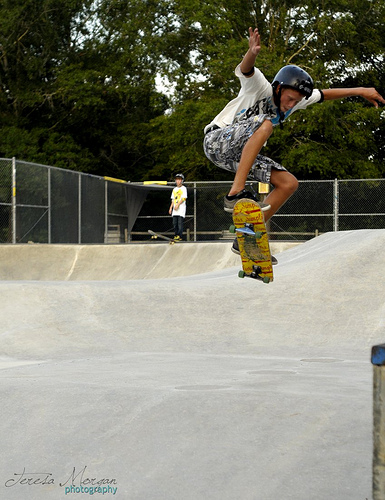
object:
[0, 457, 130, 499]
corner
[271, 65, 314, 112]
helmet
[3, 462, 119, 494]
name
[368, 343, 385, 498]
rail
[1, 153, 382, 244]
fence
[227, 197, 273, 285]
skateboard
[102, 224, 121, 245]
can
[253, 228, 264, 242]
wheels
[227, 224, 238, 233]
wheel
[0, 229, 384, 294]
ramp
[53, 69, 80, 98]
leaves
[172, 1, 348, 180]
tree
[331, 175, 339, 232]
post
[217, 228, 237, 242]
bench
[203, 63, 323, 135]
shirt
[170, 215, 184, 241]
jeans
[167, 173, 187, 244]
skater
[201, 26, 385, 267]
boy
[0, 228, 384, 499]
skatepark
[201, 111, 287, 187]
shorts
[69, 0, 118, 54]
sky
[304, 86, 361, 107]
arms